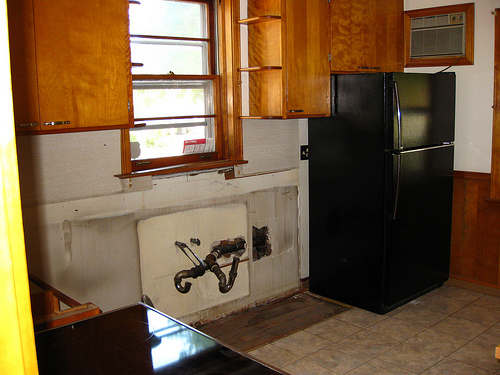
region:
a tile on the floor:
[245, 340, 297, 372]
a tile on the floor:
[276, 327, 324, 358]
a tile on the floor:
[311, 312, 358, 350]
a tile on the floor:
[336, 302, 380, 325]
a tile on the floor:
[286, 357, 329, 372]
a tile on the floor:
[304, 344, 370, 371]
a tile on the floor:
[336, 325, 401, 354]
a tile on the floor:
[368, 311, 419, 339]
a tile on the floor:
[376, 340, 443, 372]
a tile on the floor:
[428, 315, 488, 345]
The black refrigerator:
[305, 66, 460, 321]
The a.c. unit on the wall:
[405, 12, 473, 62]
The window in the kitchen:
[121, 0, 229, 168]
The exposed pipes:
[172, 230, 243, 295]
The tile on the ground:
[248, 281, 496, 373]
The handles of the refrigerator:
[388, 76, 404, 226]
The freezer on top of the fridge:
[386, 66, 457, 152]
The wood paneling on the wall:
[437, 165, 499, 299]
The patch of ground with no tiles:
[201, 288, 350, 351]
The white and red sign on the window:
[180, 134, 216, 156]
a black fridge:
[315, 60, 465, 309]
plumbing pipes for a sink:
[140, 221, 304, 305]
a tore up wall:
[37, 207, 361, 310]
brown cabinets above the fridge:
[254, 2, 450, 117]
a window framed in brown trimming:
[118, 6, 262, 177]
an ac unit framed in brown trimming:
[396, 0, 479, 63]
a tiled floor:
[278, 328, 432, 373]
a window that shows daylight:
[132, 14, 226, 148]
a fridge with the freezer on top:
[319, 53, 478, 305]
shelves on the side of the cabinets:
[235, 10, 303, 124]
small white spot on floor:
[402, 291, 442, 321]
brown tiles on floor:
[301, 322, 390, 347]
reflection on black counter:
[159, 320, 220, 373]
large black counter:
[90, 290, 250, 373]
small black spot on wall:
[239, 215, 301, 261]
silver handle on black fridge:
[373, 70, 421, 181]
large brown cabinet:
[27, 65, 150, 138]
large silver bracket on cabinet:
[32, 108, 109, 123]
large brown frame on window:
[133, 50, 234, 114]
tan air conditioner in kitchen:
[402, 5, 489, 77]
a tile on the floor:
[352, 358, 402, 373]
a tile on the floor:
[413, 322, 463, 353]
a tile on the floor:
[397, 301, 448, 325]